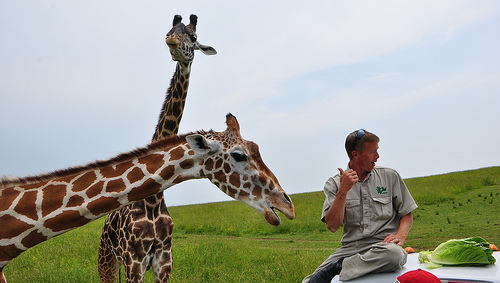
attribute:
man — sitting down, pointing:
[302, 131, 420, 282]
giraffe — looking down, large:
[1, 113, 295, 282]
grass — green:
[0, 165, 500, 282]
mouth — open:
[271, 206, 292, 223]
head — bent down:
[184, 113, 295, 227]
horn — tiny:
[172, 14, 183, 25]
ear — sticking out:
[196, 41, 219, 57]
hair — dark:
[2, 130, 207, 187]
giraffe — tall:
[97, 13, 217, 282]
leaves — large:
[417, 236, 499, 270]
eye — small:
[189, 35, 200, 46]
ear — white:
[186, 132, 225, 155]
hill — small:
[5, 166, 499, 282]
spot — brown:
[43, 184, 66, 217]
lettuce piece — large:
[415, 236, 499, 269]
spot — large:
[44, 211, 93, 233]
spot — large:
[2, 213, 34, 239]